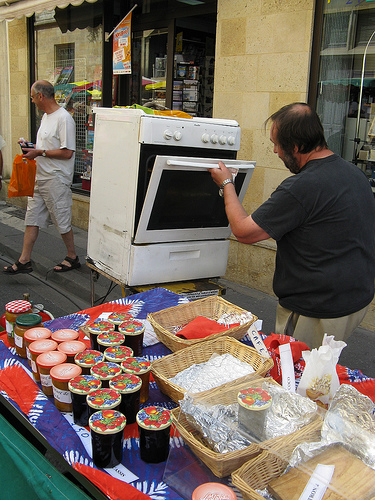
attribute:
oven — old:
[86, 104, 257, 289]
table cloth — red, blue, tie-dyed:
[3, 286, 374, 500]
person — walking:
[5, 79, 81, 274]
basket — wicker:
[146, 295, 259, 353]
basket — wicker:
[149, 336, 274, 403]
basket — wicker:
[167, 377, 322, 482]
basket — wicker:
[232, 415, 374, 500]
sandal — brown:
[2, 260, 35, 274]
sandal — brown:
[52, 255, 83, 275]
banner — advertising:
[110, 13, 134, 76]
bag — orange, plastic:
[4, 156, 39, 200]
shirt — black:
[251, 152, 374, 319]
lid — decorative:
[136, 404, 171, 432]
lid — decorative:
[88, 410, 129, 433]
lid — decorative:
[86, 388, 121, 410]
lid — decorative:
[72, 374, 100, 395]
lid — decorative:
[111, 372, 143, 396]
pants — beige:
[23, 171, 74, 237]